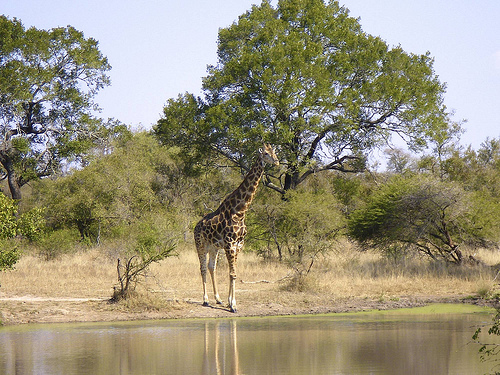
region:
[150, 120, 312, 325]
this is a giraffe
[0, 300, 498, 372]
this is a stram of water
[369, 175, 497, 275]
this is a tree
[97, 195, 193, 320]
this is a tree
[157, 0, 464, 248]
this is a tree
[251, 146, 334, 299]
this is a tree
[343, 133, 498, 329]
this is a tree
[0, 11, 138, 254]
this is a tree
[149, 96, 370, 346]
a giraffe at the water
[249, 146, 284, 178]
the head of giraffe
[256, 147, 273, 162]
the eye of a giraffe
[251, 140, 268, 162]
the ear of a giraffe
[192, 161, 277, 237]
the neck of a giraffe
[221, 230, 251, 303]
the legs of a giraffe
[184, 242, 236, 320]
the back legs of a giraffe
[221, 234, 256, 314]
the front legs of a giraffe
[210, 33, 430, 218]
a tall tree in the background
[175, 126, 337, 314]
a tall giraffe at the waters edge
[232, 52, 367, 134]
the green tree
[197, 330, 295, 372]
the water is brown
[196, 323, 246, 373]
a reflection in the water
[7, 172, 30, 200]
a tree trunk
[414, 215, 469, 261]
tree branches in the tree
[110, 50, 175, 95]
the sky is clear and blue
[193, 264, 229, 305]
the giraffes legs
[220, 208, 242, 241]
patterns on the giraffe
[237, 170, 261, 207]
the neck of the giraffe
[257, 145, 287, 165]
the giraffes head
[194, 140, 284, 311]
the giraffe is spotted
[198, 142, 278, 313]
the giraffe is near the water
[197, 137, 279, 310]
The giraffe is standing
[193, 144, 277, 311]
The giraffe is brown and yellow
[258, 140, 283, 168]
The giraffe has two horns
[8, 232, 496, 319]
The grass is brown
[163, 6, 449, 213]
Tall tree behind giraffe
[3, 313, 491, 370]
The water is still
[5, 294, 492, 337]
Green moss growing on edge of water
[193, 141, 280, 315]
The giraffe is on top of dirt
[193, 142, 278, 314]
Giraffe standing by the water.